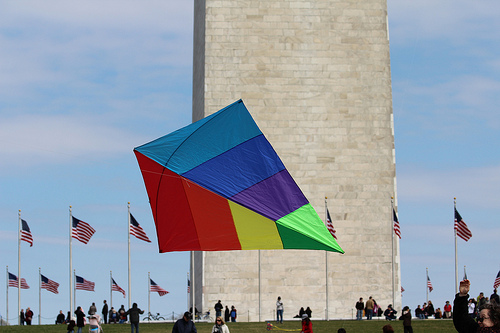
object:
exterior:
[206, 2, 391, 320]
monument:
[188, 0, 401, 320]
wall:
[348, 177, 370, 211]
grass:
[320, 319, 352, 327]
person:
[214, 300, 223, 317]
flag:
[493, 270, 500, 290]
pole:
[453, 196, 459, 308]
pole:
[324, 251, 329, 321]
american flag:
[19, 218, 33, 247]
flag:
[132, 98, 345, 255]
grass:
[343, 316, 355, 321]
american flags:
[75, 275, 95, 292]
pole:
[71, 269, 77, 326]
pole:
[17, 209, 21, 327]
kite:
[132, 98, 347, 255]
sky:
[0, 0, 500, 310]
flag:
[111, 277, 126, 298]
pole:
[108, 270, 112, 322]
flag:
[40, 273, 60, 294]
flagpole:
[67, 238, 74, 324]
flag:
[188, 279, 190, 293]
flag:
[7, 271, 30, 289]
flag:
[451, 197, 471, 312]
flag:
[150, 277, 170, 297]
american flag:
[455, 207, 474, 244]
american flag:
[393, 207, 402, 238]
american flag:
[326, 208, 338, 240]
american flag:
[129, 211, 152, 243]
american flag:
[71, 215, 96, 245]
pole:
[425, 266, 429, 301]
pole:
[391, 234, 396, 300]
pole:
[257, 249, 260, 322]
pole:
[147, 272, 151, 317]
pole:
[69, 211, 73, 314]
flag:
[427, 275, 434, 292]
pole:
[464, 266, 467, 279]